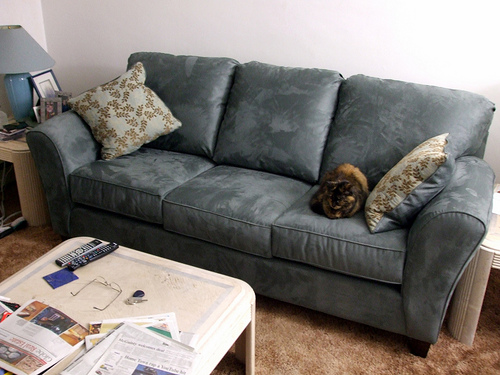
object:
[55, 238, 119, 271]
remote controls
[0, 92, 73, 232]
table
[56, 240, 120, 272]
remote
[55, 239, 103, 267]
remote control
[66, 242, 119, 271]
remote control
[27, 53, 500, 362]
couch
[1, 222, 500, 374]
carpet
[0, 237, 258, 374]
table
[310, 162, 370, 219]
cat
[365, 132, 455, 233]
throw pillow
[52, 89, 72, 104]
flower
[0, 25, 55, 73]
lampshade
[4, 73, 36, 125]
lamp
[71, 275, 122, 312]
eyeglasses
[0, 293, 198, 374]
papers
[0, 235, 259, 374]
coffee table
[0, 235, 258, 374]
table top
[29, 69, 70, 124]
pictures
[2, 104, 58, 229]
end table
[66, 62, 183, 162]
pillow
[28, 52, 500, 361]
sofa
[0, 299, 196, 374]
newspaper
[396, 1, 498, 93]
light reflection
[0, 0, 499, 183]
wall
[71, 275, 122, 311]
glasses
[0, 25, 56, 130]
lamp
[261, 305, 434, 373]
carpet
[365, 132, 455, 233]
pillow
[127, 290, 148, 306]
keys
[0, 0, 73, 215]
corner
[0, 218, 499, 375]
floor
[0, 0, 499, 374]
living room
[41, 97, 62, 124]
picture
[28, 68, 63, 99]
picture